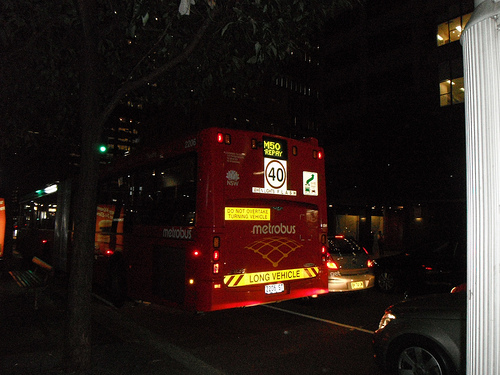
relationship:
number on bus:
[268, 162, 285, 184] [53, 126, 330, 323]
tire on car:
[382, 336, 452, 373] [365, 279, 463, 374]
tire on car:
[382, 336, 452, 373] [320, 229, 377, 295]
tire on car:
[382, 336, 452, 373] [368, 246, 456, 293]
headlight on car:
[367, 305, 399, 337] [328, 226, 376, 299]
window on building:
[435, 71, 462, 111] [321, 0, 472, 263]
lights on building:
[334, 200, 439, 220] [327, 7, 461, 244]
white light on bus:
[40, 183, 60, 197] [10, 109, 334, 324]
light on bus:
[208, 246, 227, 263] [1, 100, 333, 315]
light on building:
[438, 79, 465, 104] [377, 35, 461, 261]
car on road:
[323, 233, 376, 294] [301, 307, 371, 362]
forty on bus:
[264, 156, 287, 184] [166, 151, 328, 294]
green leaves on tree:
[226, 19, 281, 62] [128, 8, 328, 110]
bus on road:
[100, 75, 379, 359] [135, 313, 345, 364]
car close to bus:
[323, 233, 376, 294] [156, 99, 334, 269]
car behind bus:
[368, 284, 469, 374] [7, 122, 331, 314]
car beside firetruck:
[326, 230, 380, 295] [15, 124, 328, 315]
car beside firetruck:
[373, 230, 465, 292] [15, 124, 328, 315]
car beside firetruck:
[368, 284, 468, 374] [15, 124, 328, 315]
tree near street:
[70, 165, 111, 370] [105, 302, 183, 348]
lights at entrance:
[334, 200, 439, 220] [338, 214, 378, 236]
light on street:
[92, 146, 112, 160] [28, 212, 452, 324]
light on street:
[27, 184, 49, 197] [28, 212, 452, 324]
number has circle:
[269, 167, 284, 182] [259, 164, 272, 184]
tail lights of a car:
[330, 255, 379, 277] [315, 230, 390, 317]